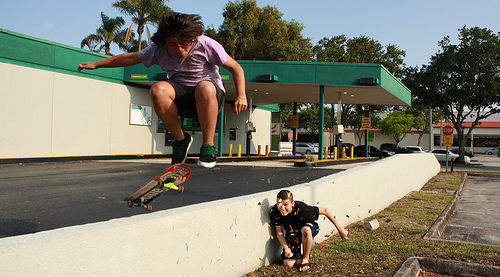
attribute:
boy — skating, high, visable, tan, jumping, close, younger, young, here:
[122, 9, 258, 161]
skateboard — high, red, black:
[121, 153, 201, 221]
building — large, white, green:
[0, 29, 112, 184]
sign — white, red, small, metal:
[434, 116, 460, 147]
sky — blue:
[375, 3, 459, 42]